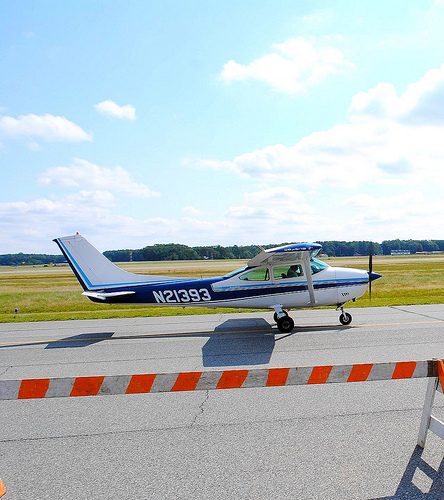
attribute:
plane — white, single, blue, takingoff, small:
[53, 233, 384, 334]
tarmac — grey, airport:
[2, 308, 444, 500]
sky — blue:
[3, 2, 213, 100]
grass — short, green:
[391, 263, 444, 307]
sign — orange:
[1, 359, 444, 401]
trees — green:
[105, 243, 254, 262]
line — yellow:
[2, 318, 443, 347]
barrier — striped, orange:
[2, 359, 443, 405]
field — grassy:
[2, 262, 442, 322]